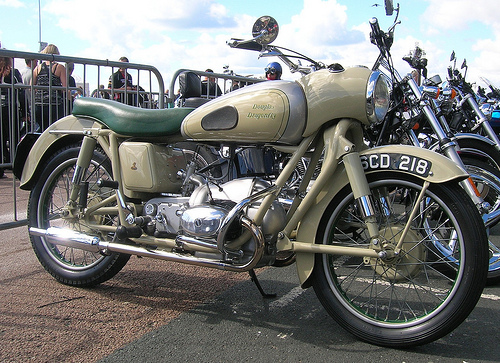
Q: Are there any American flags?
A: No, there are no American flags.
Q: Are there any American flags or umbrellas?
A: No, there are no American flags or umbrellas.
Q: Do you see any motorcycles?
A: Yes, there is a motorcycle.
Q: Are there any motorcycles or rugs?
A: Yes, there is a motorcycle.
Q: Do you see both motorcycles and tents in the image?
A: No, there is a motorcycle but no tents.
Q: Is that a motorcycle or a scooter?
A: That is a motorcycle.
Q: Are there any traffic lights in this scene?
A: No, there are no traffic lights.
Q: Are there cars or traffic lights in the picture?
A: No, there are no traffic lights or cars.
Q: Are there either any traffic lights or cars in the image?
A: No, there are no traffic lights or cars.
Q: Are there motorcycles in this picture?
A: Yes, there is a motorcycle.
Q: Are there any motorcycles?
A: Yes, there is a motorcycle.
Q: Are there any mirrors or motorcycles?
A: Yes, there is a motorcycle.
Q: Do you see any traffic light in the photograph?
A: No, there are no traffic lights.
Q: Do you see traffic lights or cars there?
A: No, there are no traffic lights or cars.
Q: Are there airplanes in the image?
A: No, there are no airplanes.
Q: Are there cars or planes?
A: No, there are no planes or cars.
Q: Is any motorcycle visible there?
A: Yes, there is a motorcycle.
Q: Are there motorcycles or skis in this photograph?
A: Yes, there is a motorcycle.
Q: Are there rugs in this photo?
A: No, there are no rugs.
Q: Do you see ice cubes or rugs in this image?
A: No, there are no rugs or ice cubes.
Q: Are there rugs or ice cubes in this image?
A: No, there are no rugs or ice cubes.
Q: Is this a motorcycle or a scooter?
A: This is a motorcycle.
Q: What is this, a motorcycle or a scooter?
A: This is a motorcycle.